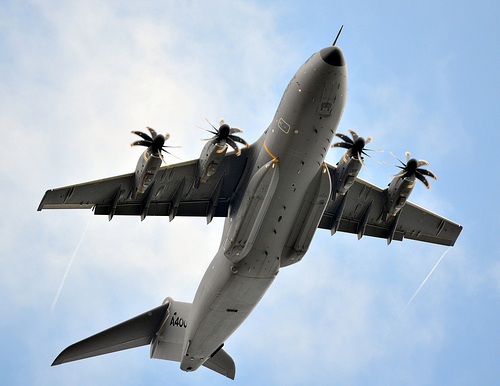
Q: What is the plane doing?
A: Flying.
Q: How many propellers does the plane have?
A: Four.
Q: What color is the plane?
A: White.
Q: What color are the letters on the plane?
A: Black.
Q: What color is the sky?
A: Light blue.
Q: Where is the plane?
A: In the sky.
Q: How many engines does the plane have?
A: Four.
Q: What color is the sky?
A: Blue.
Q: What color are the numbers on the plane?
A: Black.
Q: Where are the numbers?
A: On the stabilizer.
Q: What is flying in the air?
A: A plane.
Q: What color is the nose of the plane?
A: Black.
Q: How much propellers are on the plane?
A: Four.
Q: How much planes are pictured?
A: One.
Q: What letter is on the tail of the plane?
A: A.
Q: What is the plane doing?
A: Flying.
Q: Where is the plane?
A: In the air.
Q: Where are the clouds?
A: Above the plane.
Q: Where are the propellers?
A: On the wings.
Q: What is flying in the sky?
A: A plane.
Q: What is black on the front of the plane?
A: The plane's nose.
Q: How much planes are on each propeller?
A: Eight.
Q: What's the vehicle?
A: Airplane.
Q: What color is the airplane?
A: Gray.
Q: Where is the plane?
A: In the sky.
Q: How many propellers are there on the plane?
A: Four.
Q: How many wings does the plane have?
A: Two.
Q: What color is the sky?
A: Blue.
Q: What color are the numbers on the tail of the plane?
A: Black.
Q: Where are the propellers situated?
A: On the wings.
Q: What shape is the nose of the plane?
A: Cone shaped.